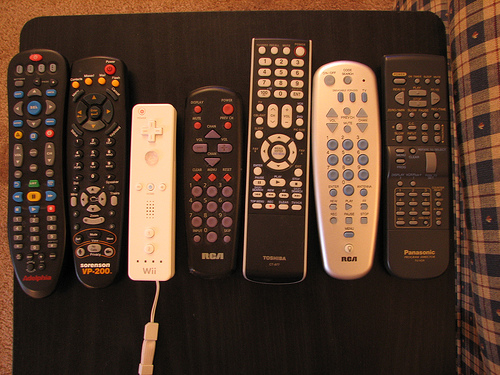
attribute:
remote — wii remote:
[125, 99, 174, 284]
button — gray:
[395, 87, 407, 108]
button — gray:
[405, 85, 430, 97]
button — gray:
[405, 98, 430, 110]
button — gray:
[427, 90, 442, 107]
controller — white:
[121, 188, 185, 308]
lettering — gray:
[132, 255, 167, 300]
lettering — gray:
[193, 248, 235, 263]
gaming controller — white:
[120, 99, 181, 371]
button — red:
[191, 172, 201, 182]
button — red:
[205, 172, 216, 182]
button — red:
[221, 170, 231, 182]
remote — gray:
[305, 55, 381, 281]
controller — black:
[308, 55, 383, 291]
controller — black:
[65, 48, 133, 296]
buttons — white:
[219, 36, 391, 326]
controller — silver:
[310, 63, 380, 279]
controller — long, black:
[11, 42, 68, 298]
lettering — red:
[18, 273, 53, 280]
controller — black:
[4, 47, 70, 301]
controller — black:
[378, 52, 453, 284]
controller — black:
[314, 58, 381, 283]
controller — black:
[237, 34, 314, 287]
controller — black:
[125, 104, 177, 285]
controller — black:
[244, 29, 319, 283]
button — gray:
[355, 137, 369, 155]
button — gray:
[424, 148, 437, 174]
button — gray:
[83, 184, 105, 199]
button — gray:
[86, 246, 103, 259]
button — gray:
[260, 103, 279, 130]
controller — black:
[178, 83, 242, 283]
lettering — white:
[401, 248, 436, 257]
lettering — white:
[262, 251, 285, 261]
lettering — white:
[201, 250, 222, 260]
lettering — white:
[80, 262, 109, 266]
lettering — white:
[28, 55, 40, 61]